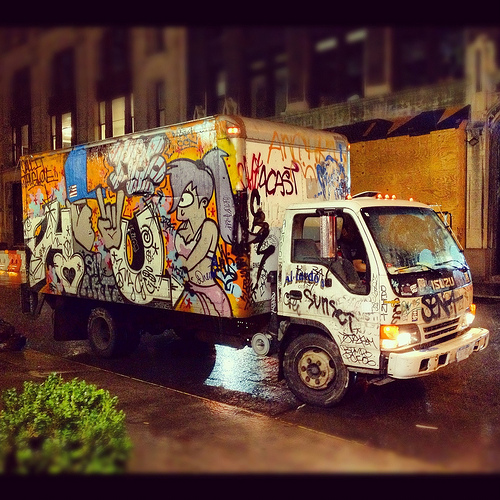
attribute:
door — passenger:
[275, 208, 382, 370]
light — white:
[397, 330, 417, 352]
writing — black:
[233, 153, 338, 203]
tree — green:
[3, 363, 124, 487]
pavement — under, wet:
[0, 273, 499, 470]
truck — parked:
[21, 97, 488, 452]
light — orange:
[375, 322, 400, 337]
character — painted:
[167, 145, 250, 317]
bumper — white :
[379, 324, 492, 379]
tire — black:
[283, 335, 350, 408]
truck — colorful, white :
[16, 109, 490, 411]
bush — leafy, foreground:
[1, 372, 131, 475]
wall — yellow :
[357, 148, 454, 183]